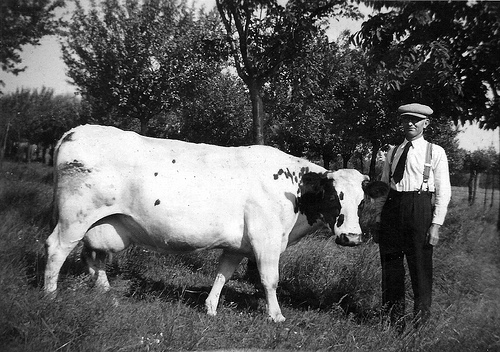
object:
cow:
[41, 124, 390, 323]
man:
[370, 102, 454, 334]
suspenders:
[416, 141, 434, 196]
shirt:
[379, 134, 452, 226]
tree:
[0, 0, 500, 208]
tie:
[391, 141, 413, 184]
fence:
[446, 172, 500, 210]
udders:
[105, 250, 117, 264]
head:
[302, 169, 393, 248]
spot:
[153, 199, 161, 208]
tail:
[48, 132, 76, 237]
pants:
[380, 187, 435, 331]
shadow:
[25, 250, 386, 323]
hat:
[397, 103, 434, 120]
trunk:
[249, 84, 266, 146]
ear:
[423, 118, 431, 129]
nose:
[336, 233, 367, 246]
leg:
[41, 224, 83, 298]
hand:
[425, 223, 443, 247]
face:
[401, 116, 426, 138]